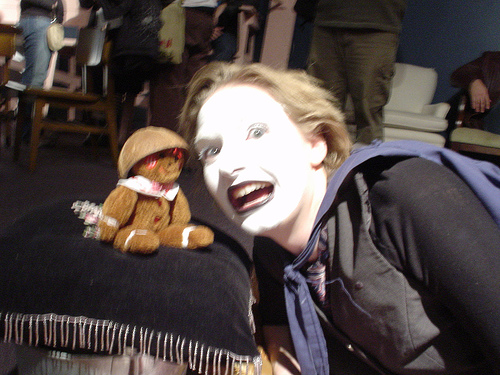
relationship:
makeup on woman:
[237, 147, 302, 182] [198, 65, 360, 262]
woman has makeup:
[198, 65, 360, 262] [237, 147, 302, 182]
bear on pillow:
[99, 124, 198, 250] [19, 169, 109, 330]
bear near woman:
[99, 124, 198, 250] [198, 65, 360, 262]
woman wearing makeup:
[198, 65, 360, 262] [237, 147, 302, 182]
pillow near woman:
[19, 169, 109, 330] [198, 65, 360, 262]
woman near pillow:
[198, 65, 360, 262] [19, 169, 109, 330]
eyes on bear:
[147, 144, 184, 170] [99, 124, 198, 250]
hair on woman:
[171, 49, 360, 253] [198, 65, 360, 262]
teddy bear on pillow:
[85, 131, 219, 258] [5, 148, 270, 372]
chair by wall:
[376, 57, 457, 161] [245, 5, 496, 132]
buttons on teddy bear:
[151, 198, 166, 234] [70, 125, 216, 253]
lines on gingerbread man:
[102, 205, 207, 252] [82, 118, 223, 250]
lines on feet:
[102, 205, 207, 252] [120, 221, 220, 256]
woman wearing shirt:
[174, 59, 500, 375] [283, 153, 496, 370]